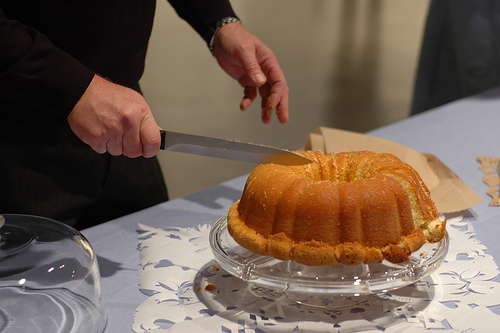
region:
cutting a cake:
[50, 22, 453, 292]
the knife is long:
[46, 20, 453, 266]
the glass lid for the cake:
[31, 202, 130, 290]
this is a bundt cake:
[144, 31, 453, 291]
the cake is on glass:
[168, 86, 465, 285]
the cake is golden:
[194, 118, 445, 331]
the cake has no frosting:
[222, 116, 448, 304]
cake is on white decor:
[148, 206, 388, 322]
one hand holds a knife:
[41, 42, 407, 262]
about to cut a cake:
[74, 45, 376, 284]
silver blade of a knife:
[161, 124, 313, 181]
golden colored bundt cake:
[230, 132, 433, 269]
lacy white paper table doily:
[122, 206, 207, 327]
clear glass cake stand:
[204, 246, 448, 302]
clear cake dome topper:
[15, 208, 120, 332]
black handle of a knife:
[137, 114, 172, 156]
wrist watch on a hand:
[199, 15, 260, 52]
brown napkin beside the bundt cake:
[298, 111, 476, 219]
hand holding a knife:
[54, 52, 210, 184]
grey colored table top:
[429, 104, 479, 148]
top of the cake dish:
[1, 211, 101, 331]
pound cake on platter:
[226, 147, 446, 261]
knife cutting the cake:
[162, 132, 312, 162]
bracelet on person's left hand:
[206, 16, 241, 37]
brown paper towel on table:
[305, 128, 414, 150]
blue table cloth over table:
[439, 100, 499, 147]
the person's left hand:
[209, 22, 295, 123]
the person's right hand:
[70, 67, 162, 170]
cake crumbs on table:
[199, 263, 223, 295]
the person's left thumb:
[241, 50, 266, 87]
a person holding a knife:
[76, 91, 308, 182]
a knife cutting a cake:
[160, 115, 445, 260]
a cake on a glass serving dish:
[196, 154, 459, 307]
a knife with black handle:
[152, 118, 209, 163]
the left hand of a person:
[206, 10, 298, 120]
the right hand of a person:
[70, 82, 159, 159]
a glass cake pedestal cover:
[0, 213, 108, 316]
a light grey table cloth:
[430, 121, 479, 154]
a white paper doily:
[135, 224, 495, 331]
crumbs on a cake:
[252, 178, 295, 211]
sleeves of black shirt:
[1, 0, 237, 117]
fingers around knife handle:
[78, 83, 310, 168]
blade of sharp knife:
[163, 130, 314, 167]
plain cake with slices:
[226, 149, 446, 261]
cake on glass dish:
[208, 151, 450, 296]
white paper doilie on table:
[136, 214, 495, 331]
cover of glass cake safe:
[1, 211, 106, 331]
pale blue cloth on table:
[1, 93, 498, 331]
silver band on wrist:
[208, 15, 240, 48]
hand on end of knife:
[91, 82, 161, 157]